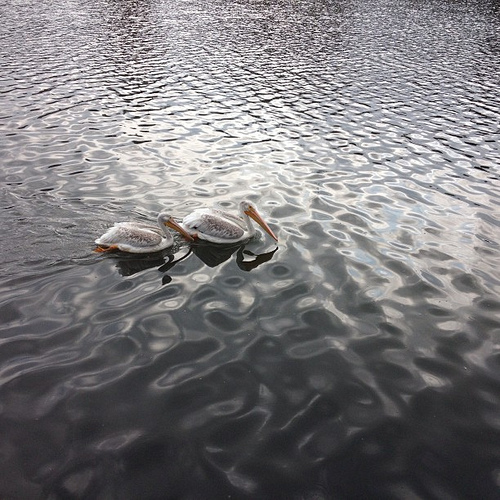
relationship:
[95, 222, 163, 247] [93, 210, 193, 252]
wing of bird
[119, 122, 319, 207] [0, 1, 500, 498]
glare of water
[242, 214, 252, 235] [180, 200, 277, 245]
neck of bird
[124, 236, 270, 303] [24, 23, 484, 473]
birds shadow of water